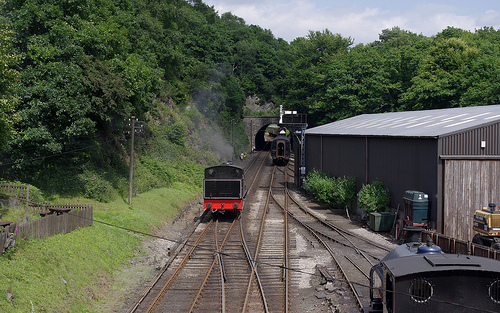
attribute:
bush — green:
[358, 182, 390, 216]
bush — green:
[331, 176, 353, 203]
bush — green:
[298, 163, 356, 215]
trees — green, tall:
[4, 5, 496, 168]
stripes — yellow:
[430, 112, 477, 127]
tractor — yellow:
[469, 202, 499, 252]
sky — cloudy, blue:
[188, 0, 499, 51]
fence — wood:
[7, 182, 117, 260]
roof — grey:
[296, 101, 496, 149]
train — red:
[200, 163, 244, 213]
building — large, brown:
[306, 105, 491, 238]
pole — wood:
[124, 116, 142, 208]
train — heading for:
[271, 137, 289, 164]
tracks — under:
[191, 220, 270, 277]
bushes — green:
[301, 168, 383, 228]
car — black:
[185, 156, 252, 243]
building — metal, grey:
[293, 99, 499, 253]